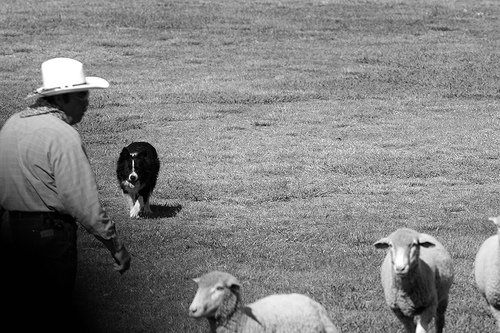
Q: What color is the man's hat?
A: White.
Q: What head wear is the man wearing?
A: A hat.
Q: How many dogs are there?
A: One.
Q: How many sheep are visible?
A: Three.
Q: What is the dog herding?
A: Sheep.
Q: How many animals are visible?
A: Four.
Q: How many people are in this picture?
A: One.